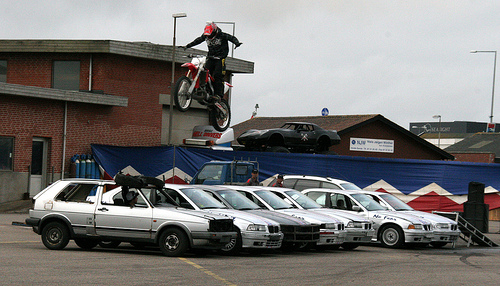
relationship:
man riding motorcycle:
[183, 22, 243, 93] [171, 48, 232, 130]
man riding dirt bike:
[183, 22, 243, 93] [167, 48, 234, 133]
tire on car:
[38, 215, 69, 249] [24, 175, 239, 250]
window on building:
[51, 59, 81, 91] [3, 31, 258, 215]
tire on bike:
[173, 75, 193, 111] [174, 51, 233, 133]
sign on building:
[348, 137, 396, 154] [251, 115, 451, 161]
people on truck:
[247, 170, 284, 187] [187, 158, 263, 185]